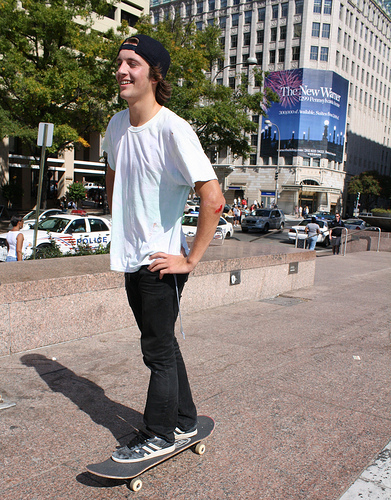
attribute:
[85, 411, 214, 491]
skateboard — black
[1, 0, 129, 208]
tree — green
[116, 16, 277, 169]
tree — green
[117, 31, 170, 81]
cap — backwards, black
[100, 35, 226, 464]
man — smiling, skateboarding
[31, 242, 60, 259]
wheel — part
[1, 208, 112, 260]
police car — white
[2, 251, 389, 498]
ground — gre, cocrete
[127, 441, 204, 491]
wheels — white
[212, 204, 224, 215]
cut — open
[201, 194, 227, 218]
elbow — bleeding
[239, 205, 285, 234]
suv — silver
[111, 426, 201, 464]
soles — white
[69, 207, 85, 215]
light — red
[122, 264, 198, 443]
jeans — black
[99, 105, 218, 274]
shirt — white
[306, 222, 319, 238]
shirt — gra, gre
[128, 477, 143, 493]
wheel — white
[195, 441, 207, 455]
wheel — white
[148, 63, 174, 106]
hair — log